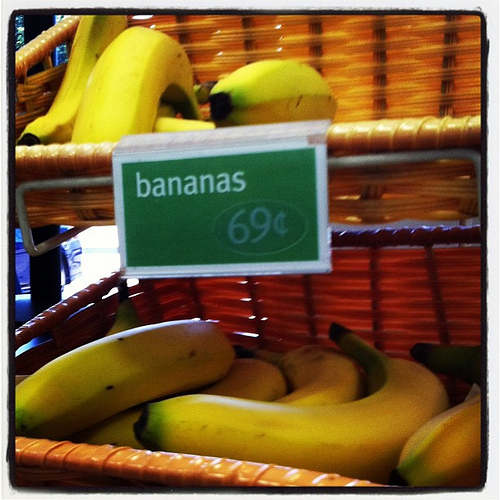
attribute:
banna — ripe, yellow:
[143, 326, 447, 470]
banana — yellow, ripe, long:
[66, 24, 208, 134]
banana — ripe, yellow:
[9, 310, 240, 431]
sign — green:
[108, 136, 342, 276]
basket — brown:
[336, 19, 483, 216]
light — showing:
[71, 232, 125, 281]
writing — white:
[134, 167, 246, 201]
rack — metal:
[13, 167, 353, 184]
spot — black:
[105, 370, 117, 404]